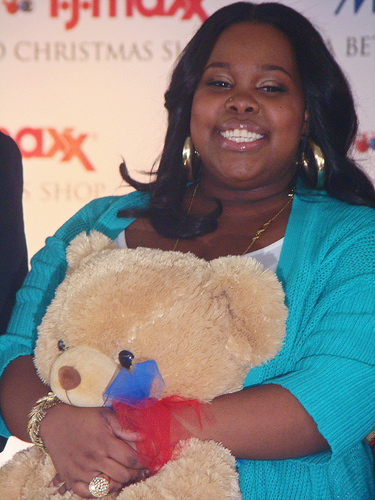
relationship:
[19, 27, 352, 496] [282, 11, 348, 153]
woman with hair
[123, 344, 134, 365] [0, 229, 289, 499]
eye of bear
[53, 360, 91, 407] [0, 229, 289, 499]
nose of bear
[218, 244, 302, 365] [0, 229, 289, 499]
ear of bear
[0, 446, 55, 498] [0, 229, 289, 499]
arm of bear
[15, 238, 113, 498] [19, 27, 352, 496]
arm of woman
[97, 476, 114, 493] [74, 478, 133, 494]
ring in finger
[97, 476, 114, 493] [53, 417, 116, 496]
ring on hand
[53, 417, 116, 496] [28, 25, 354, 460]
hand of lady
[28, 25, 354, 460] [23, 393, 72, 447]
lady wearing bracelet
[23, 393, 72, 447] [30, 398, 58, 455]
bracelet on wrist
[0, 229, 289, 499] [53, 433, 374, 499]
bear on lap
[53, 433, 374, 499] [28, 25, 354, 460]
lap of lady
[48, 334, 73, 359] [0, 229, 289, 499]
eye of bear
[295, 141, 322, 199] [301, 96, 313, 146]
earrings on ear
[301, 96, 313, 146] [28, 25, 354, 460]
ear of lady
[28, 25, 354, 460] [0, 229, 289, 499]
lady holding bear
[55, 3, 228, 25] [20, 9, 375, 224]
advertisement on wall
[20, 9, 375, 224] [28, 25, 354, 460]
wall behind lady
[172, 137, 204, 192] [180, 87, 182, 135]
earring in ear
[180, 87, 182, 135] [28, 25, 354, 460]
ear of lady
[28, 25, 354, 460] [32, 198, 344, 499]
lady wearing jacket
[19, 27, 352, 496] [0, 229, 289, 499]
woman holding bear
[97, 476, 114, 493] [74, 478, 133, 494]
ring on finger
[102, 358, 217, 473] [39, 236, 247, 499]
net on bear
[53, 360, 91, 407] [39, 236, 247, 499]
nose of bear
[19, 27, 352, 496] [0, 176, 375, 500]
woman wears jacket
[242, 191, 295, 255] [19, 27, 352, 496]
chain on woman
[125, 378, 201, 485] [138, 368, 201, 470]
net around wrist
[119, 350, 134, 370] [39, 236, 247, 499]
eye of bear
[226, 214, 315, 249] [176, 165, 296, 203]
chain on neck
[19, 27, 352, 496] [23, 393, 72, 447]
woman wearing bracelet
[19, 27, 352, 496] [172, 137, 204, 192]
woman wearing earring